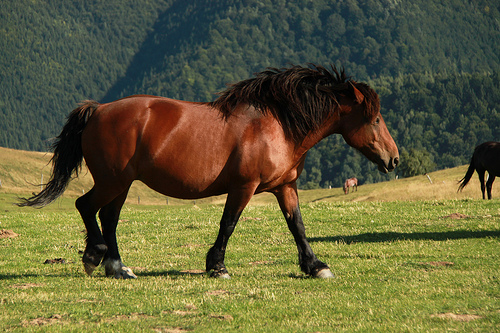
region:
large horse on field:
[41, 71, 418, 286]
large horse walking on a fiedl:
[15, 74, 408, 296]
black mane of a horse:
[227, 68, 323, 119]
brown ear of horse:
[343, 79, 368, 103]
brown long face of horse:
[355, 119, 410, 176]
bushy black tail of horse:
[20, 130, 80, 201]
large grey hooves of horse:
[312, 269, 334, 282]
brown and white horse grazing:
[338, 177, 365, 196]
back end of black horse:
[449, 142, 498, 203]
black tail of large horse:
[454, 158, 477, 191]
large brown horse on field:
[17, 70, 416, 290]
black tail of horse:
[27, 113, 92, 181]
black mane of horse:
[195, 66, 354, 128]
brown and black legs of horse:
[188, 175, 317, 265]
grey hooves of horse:
[317, 265, 336, 280]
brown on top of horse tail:
[69, 96, 99, 120]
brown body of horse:
[82, 97, 299, 179]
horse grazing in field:
[334, 168, 364, 198]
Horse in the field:
[30, 52, 427, 288]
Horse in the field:
[330, 162, 362, 194]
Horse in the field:
[460, 113, 497, 203]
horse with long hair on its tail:
[25, 95, 101, 185]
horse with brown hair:
[236, 72, 377, 130]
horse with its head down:
[337, 170, 367, 195]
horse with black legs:
[210, 211, 235, 277]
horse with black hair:
[457, 142, 485, 200]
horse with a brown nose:
[373, 145, 404, 176]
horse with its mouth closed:
[378, 149, 394, 177]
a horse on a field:
[78, 52, 495, 329]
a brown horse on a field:
[55, 58, 383, 326]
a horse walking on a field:
[49, 39, 388, 321]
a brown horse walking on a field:
[29, 45, 439, 329]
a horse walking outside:
[58, 33, 472, 325]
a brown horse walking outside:
[42, 29, 497, 324]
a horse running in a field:
[71, 45, 411, 330]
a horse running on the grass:
[67, 18, 453, 233]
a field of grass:
[23, 132, 436, 326]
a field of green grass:
[116, 146, 471, 323]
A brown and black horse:
[58, 94, 413, 280]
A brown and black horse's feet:
[280, 189, 337, 276]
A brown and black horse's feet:
[195, 187, 248, 287]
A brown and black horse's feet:
[77, 166, 109, 266]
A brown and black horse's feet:
[101, 191, 138, 278]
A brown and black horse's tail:
[38, 91, 100, 201]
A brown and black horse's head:
[290, 73, 432, 171]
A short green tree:
[435, 88, 460, 120]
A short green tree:
[358, 31, 383, 58]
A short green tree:
[254, 14, 270, 36]